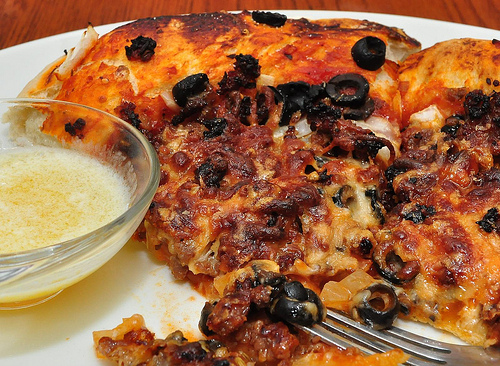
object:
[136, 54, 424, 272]
pieces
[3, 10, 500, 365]
pizza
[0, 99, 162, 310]
bowl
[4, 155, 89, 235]
butter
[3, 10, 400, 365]
slice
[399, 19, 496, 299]
slice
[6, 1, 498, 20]
table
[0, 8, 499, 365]
plate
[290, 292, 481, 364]
fork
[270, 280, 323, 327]
olives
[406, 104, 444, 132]
onions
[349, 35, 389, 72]
olive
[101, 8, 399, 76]
crust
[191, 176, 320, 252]
cheese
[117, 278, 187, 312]
grease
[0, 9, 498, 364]
food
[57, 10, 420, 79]
edge